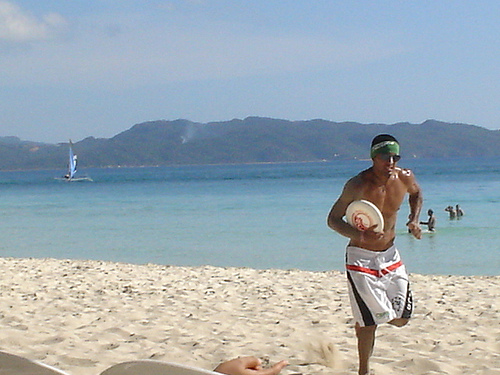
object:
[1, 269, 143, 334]
beach sand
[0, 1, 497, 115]
sky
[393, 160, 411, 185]
wall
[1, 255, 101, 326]
sand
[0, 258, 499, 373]
beach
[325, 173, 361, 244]
arm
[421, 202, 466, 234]
people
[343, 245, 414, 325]
swimsuit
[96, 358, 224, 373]
chair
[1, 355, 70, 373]
chair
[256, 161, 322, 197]
sea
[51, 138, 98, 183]
sail boat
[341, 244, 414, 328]
shorts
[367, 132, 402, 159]
head band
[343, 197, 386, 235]
frisbee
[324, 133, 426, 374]
man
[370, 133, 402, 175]
head